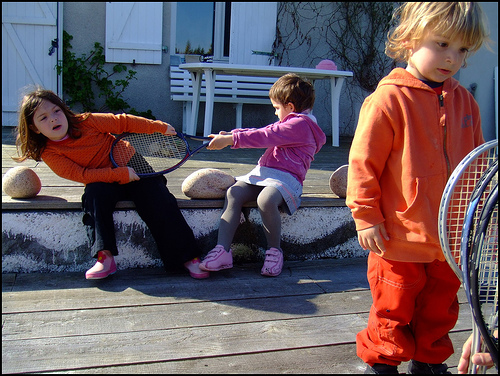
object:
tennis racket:
[110, 131, 213, 177]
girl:
[198, 73, 326, 277]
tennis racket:
[437, 138, 500, 375]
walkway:
[1, 256, 500, 376]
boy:
[344, 0, 490, 376]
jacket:
[344, 67, 491, 264]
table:
[179, 62, 354, 147]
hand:
[457, 328, 498, 375]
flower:
[97, 252, 106, 264]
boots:
[199, 244, 233, 272]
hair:
[385, 0, 491, 60]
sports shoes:
[85, 250, 119, 280]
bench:
[169, 65, 309, 135]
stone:
[181, 166, 236, 198]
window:
[169, 2, 231, 61]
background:
[0, 0, 500, 273]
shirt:
[37, 112, 169, 184]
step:
[0, 207, 500, 274]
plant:
[46, 30, 157, 122]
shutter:
[104, 0, 163, 65]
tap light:
[316, 59, 338, 71]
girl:
[15, 90, 211, 280]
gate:
[1, 0, 64, 127]